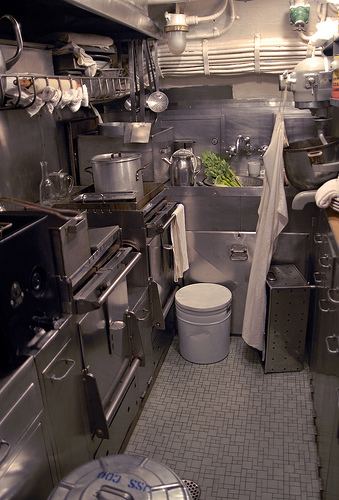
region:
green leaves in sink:
[186, 146, 258, 203]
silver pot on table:
[84, 136, 159, 220]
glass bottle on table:
[35, 155, 83, 215]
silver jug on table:
[154, 135, 212, 198]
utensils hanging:
[122, 30, 171, 153]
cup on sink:
[239, 153, 277, 186]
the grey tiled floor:
[122, 322, 315, 498]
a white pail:
[169, 278, 237, 368]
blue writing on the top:
[96, 468, 155, 496]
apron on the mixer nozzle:
[239, 66, 289, 355]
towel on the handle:
[173, 202, 191, 281]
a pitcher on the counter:
[51, 169, 75, 198]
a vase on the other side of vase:
[38, 157, 55, 206]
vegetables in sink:
[198, 144, 246, 188]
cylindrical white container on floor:
[174, 279, 236, 368]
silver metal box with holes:
[254, 261, 314, 377]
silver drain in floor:
[178, 475, 203, 498]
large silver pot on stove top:
[83, 150, 151, 200]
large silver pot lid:
[87, 150, 143, 163]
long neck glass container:
[36, 159, 57, 206]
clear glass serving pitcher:
[50, 168, 74, 200]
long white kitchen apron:
[239, 81, 291, 357]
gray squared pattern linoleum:
[118, 330, 325, 498]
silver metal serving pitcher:
[161, 146, 204, 188]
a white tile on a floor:
[203, 458, 211, 465]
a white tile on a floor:
[184, 448, 196, 463]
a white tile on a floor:
[268, 447, 281, 458]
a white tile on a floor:
[232, 464, 244, 472]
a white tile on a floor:
[290, 483, 301, 498]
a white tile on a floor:
[289, 454, 298, 461]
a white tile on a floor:
[246, 432, 261, 444]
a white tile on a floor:
[222, 460, 235, 465]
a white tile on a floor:
[218, 487, 239, 496]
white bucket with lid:
[172, 281, 240, 367]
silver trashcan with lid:
[55, 453, 190, 499]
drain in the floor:
[183, 473, 198, 497]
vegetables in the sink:
[202, 150, 246, 184]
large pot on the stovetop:
[86, 151, 144, 200]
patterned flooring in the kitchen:
[124, 318, 312, 499]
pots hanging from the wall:
[118, 38, 168, 114]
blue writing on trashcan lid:
[95, 470, 147, 498]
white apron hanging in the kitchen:
[241, 79, 289, 359]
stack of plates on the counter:
[331, 198, 338, 219]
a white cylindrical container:
[167, 274, 240, 373]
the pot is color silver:
[78, 144, 154, 212]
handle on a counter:
[49, 347, 78, 383]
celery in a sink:
[187, 143, 267, 199]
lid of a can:
[34, 448, 202, 498]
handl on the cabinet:
[47, 349, 82, 389]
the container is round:
[168, 272, 236, 374]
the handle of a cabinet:
[50, 350, 79, 389]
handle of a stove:
[77, 241, 145, 313]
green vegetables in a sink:
[196, 136, 260, 202]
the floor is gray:
[158, 377, 306, 477]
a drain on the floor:
[181, 472, 202, 499]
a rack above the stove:
[0, 42, 170, 241]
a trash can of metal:
[48, 445, 195, 498]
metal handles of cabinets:
[305, 229, 338, 356]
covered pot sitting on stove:
[83, 151, 144, 214]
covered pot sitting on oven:
[83, 151, 146, 209]